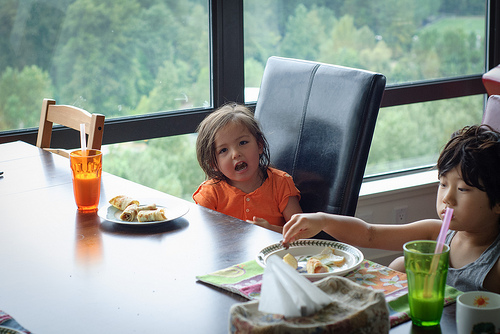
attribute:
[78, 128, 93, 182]
straw — white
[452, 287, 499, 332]
coffee mug — white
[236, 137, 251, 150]
eye — open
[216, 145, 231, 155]
eye — open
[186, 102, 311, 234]
girl — little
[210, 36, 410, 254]
chair — leather, black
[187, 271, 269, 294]
placemat — handmade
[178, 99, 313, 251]
girl — little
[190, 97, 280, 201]
girl — looking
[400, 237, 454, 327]
cup — green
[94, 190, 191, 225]
plate — white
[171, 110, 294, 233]
girl — little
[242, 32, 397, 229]
chair — high back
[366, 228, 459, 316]
glass — green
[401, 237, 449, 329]
glass — green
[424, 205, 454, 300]
straw — pink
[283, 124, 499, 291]
boy — little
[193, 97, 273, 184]
hair — brown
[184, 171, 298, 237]
shirt — orange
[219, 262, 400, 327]
cover — handcrafted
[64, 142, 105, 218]
glass — orange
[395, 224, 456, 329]
glass — green